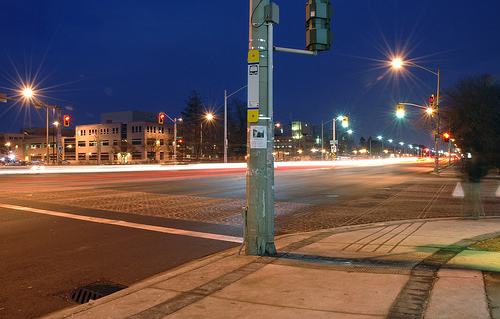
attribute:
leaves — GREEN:
[446, 92, 474, 149]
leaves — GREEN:
[461, 99, 482, 125]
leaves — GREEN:
[188, 94, 201, 112]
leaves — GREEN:
[206, 111, 228, 160]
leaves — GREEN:
[465, 106, 478, 154]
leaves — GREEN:
[457, 95, 481, 137]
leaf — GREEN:
[466, 110, 471, 113]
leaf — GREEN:
[481, 107, 483, 109]